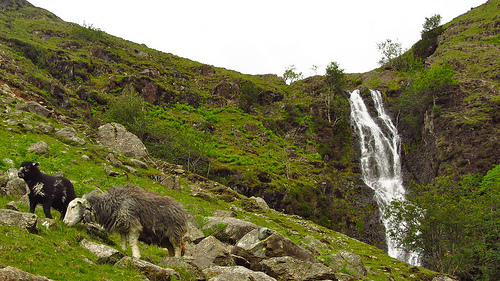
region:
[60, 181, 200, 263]
sheep on the side of a hill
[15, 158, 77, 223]
sheep on the side of a hill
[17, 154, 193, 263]
baby sheep with mother sheep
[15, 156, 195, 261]
a black sheep with a white sheep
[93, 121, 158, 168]
large boulder in the grass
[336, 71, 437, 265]
waterfall on the side of a hill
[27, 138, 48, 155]
boulder stuck in the ground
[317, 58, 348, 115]
tree with green leaves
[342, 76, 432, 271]
water cascading over a cliff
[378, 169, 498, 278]
tree with green leaves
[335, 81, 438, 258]
white water of the waterfall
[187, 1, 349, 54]
white over cast skies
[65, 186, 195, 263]
a grey sheep on a hillside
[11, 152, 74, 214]
black sheep on a hillside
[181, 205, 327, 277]
grey rocks with moss growing on them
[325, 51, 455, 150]
trees growing on the sides of the waterfall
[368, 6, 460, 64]
trees growing on top of the hill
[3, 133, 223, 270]
two sheep standing on a hillside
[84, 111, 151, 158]
large grey rock on the hillside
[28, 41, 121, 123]
black rocks of the hillside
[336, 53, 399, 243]
A waterfalls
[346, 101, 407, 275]
A waterfalls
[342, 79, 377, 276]
A waterfalls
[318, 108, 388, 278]
A waterfalls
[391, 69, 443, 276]
A waterfalls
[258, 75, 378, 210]
A waterfalls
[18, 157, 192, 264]
Sheep climb rocky hill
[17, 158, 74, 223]
Sheep is black and white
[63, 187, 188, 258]
sheep is white and gray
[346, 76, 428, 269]
Natural waterfall on right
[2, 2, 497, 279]
Rocks are black, white, and brown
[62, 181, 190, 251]
Sheep has long coat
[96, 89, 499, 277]
Trees line back of closest hill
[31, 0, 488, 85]
the sky is overcast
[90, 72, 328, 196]
Moss grows on dark rocks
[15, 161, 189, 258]
There are two sheep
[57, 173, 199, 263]
a goat on a mountainside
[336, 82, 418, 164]
two streams of a waterfall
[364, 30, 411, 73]
a bush near a hilltop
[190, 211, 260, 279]
rocks on a hill near a goat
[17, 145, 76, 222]
a black and white goat on a hill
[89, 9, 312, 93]
a white sky above a hill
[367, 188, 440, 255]
a tree in front of a waterfall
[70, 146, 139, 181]
green grass beside some rocks on a hill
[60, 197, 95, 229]
the head of a goat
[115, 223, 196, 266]
the legs of a goat